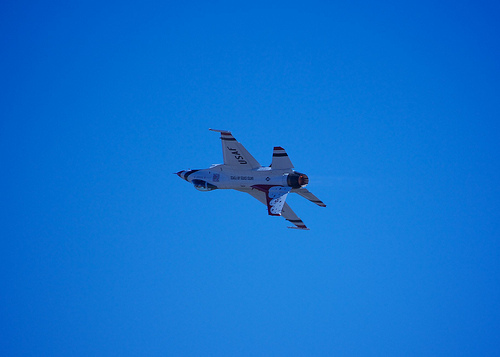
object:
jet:
[173, 128, 327, 231]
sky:
[0, 1, 498, 356]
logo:
[221, 137, 247, 168]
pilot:
[195, 177, 209, 193]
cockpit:
[195, 179, 215, 195]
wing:
[207, 129, 265, 170]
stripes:
[206, 126, 247, 150]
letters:
[225, 142, 249, 165]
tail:
[267, 135, 329, 207]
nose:
[168, 169, 196, 185]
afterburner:
[292, 166, 311, 192]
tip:
[210, 128, 234, 139]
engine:
[288, 175, 301, 193]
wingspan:
[210, 126, 312, 230]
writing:
[230, 174, 261, 182]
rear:
[265, 166, 311, 193]